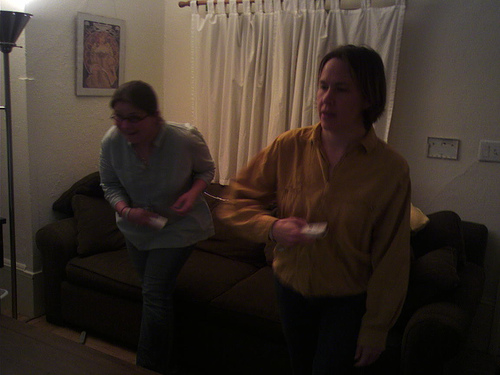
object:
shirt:
[218, 114, 427, 342]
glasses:
[108, 111, 151, 123]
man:
[216, 36, 436, 373]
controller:
[271, 214, 336, 254]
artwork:
[80, 21, 120, 88]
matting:
[75, 10, 126, 99]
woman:
[211, 41, 412, 372]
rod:
[176, 0, 299, 6]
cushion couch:
[36, 166, 489, 373]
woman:
[98, 78, 217, 372]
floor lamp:
[0, 9, 32, 319]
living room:
[0, 3, 499, 373]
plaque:
[422, 133, 461, 163]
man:
[216, 45, 411, 373]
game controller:
[297, 219, 330, 239]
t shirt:
[97, 120, 217, 254]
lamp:
[0, 9, 34, 319]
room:
[0, 2, 499, 372]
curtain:
[189, 1, 407, 186]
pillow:
[406, 241, 461, 300]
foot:
[134, 222, 184, 362]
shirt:
[84, 113, 230, 242]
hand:
[167, 192, 195, 215]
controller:
[134, 205, 174, 227]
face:
[95, 66, 175, 153]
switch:
[411, 134, 484, 236]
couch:
[30, 136, 498, 343]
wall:
[30, 8, 493, 284]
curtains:
[179, 0, 411, 207]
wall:
[18, 30, 169, 275]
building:
[0, 0, 500, 375]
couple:
[87, 59, 416, 367]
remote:
[245, 204, 357, 277]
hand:
[272, 216, 302, 249]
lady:
[39, 71, 251, 372]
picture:
[52, 9, 152, 112]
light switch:
[467, 129, 498, 186]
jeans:
[126, 240, 188, 365]